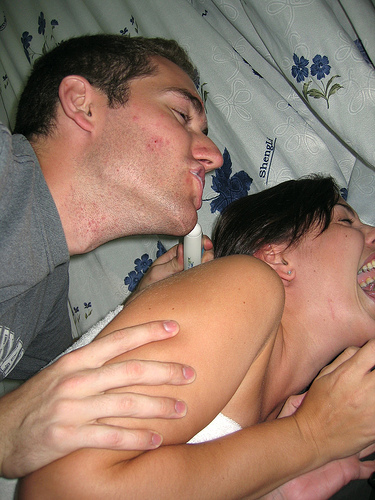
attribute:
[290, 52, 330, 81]
flowers —  blue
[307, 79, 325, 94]
stems —  green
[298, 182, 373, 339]
face —  laughing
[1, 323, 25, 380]
print —  white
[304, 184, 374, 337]
face —  girl's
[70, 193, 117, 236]
burn — of throat, from razor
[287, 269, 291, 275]
earring —  stud,  woman's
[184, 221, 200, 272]
toothbrush —  electric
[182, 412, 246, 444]
top —  white,  woman's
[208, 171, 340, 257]
hair —  woman's,  dark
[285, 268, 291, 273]
earring —  woman's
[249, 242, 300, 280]
ear —  woman's, the right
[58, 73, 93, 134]
ear — the right,  man's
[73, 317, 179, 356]
finger —  man's,  index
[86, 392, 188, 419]
finger —  man's, for ring, the right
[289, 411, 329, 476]
wrist — the right,  woman's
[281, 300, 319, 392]
neck —  woman's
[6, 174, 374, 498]
woman —  young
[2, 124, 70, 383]
shirt —  grey, tee,  gray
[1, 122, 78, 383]
shirt — gray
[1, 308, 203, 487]
hand —  man's, the right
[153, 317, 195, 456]
fingernails — pink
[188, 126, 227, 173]
nose — pointed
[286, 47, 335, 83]
flowers — purple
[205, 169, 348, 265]
hair — dark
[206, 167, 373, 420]
woman — laughing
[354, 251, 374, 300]
mouth — open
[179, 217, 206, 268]
toothbrush — electric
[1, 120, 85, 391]
shirt — gray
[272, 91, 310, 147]
design — white 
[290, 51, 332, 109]
design — gray , blue